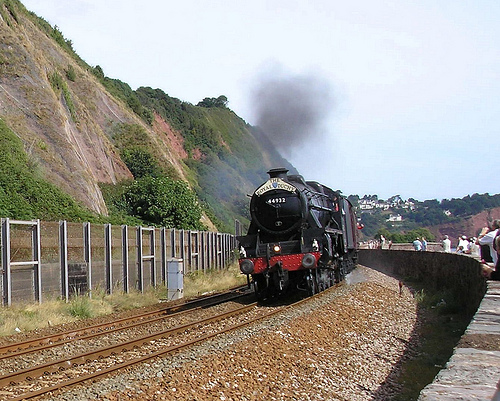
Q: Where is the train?
A: On tracks.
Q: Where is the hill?
A: Behind wood fence.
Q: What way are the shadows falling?
A: Left.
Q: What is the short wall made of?
A: Stone.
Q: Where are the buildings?
A: Behind the train.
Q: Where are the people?
A: Next to short wall.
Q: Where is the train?
A: On the track.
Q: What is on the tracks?
A: A train.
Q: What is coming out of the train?
A: Steam.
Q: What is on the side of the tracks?
A: Fences.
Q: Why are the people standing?
A: Waiting for the train.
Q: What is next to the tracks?
A: Gravel.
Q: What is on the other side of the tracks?
A: A hill.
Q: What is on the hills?
A: Trees.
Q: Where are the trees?
A: On the hill.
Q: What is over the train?
A: Smoke.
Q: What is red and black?
A: The train.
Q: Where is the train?
A: On the tracks.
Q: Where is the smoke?
A: Over the train.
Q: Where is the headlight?
A: The front of the train.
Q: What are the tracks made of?
A: Metal.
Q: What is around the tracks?
A: Gravel.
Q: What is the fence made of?
A: Metal and wire.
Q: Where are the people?
A: On the walkway.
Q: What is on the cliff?
A: Plants.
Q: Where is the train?
A: Tracks.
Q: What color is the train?
A: Red and black.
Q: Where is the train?
A: On the tracks.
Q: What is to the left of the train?
A: A mountain.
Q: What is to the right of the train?
A: People.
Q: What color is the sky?
A: Blue.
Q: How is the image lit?
A: Naturally.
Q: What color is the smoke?
A: Grey.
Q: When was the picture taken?
A: During the day.